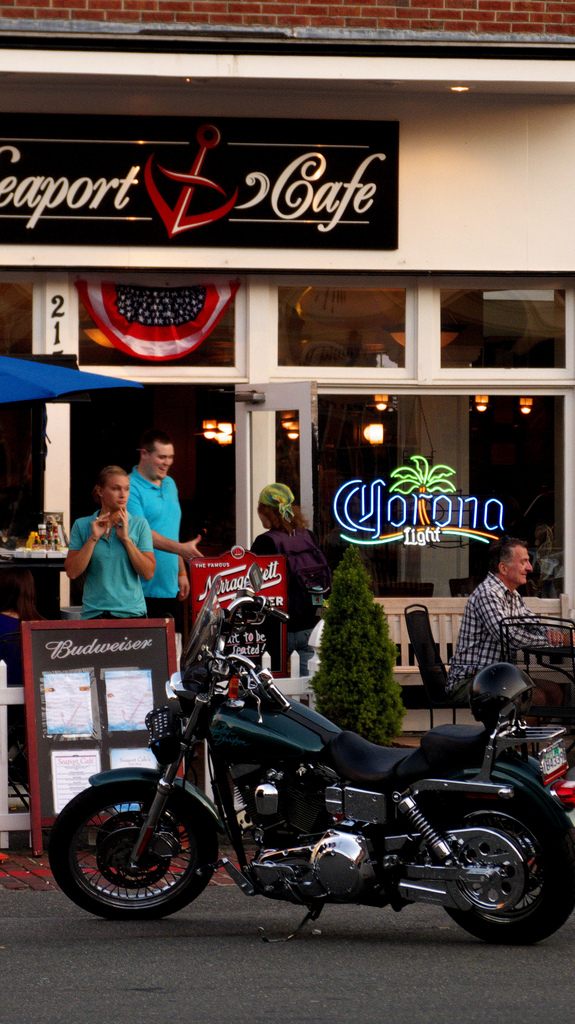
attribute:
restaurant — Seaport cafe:
[33, 41, 539, 538]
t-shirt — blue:
[67, 508, 154, 618]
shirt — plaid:
[445, 571, 567, 686]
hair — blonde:
[91, 464, 127, 504]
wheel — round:
[428, 778, 569, 948]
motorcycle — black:
[41, 582, 569, 947]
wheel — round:
[46, 755, 240, 962]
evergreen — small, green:
[310, 545, 402, 745]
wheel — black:
[435, 785, 573, 944]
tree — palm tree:
[382, 451, 455, 530]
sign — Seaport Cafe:
[0, 110, 397, 248]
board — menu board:
[19, 615, 186, 855]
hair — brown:
[134, 434, 173, 453]